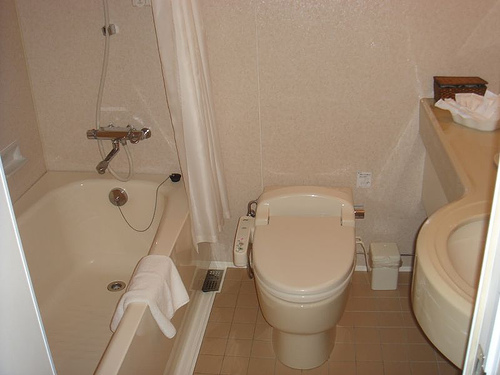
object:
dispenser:
[434, 90, 500, 132]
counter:
[430, 94, 500, 191]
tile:
[228, 320, 260, 339]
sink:
[448, 216, 484, 288]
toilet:
[249, 183, 358, 370]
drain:
[107, 280, 126, 293]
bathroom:
[0, 0, 500, 375]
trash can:
[368, 242, 402, 291]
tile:
[204, 302, 238, 322]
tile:
[228, 303, 259, 323]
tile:
[352, 324, 381, 343]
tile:
[380, 342, 410, 361]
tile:
[376, 308, 405, 327]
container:
[432, 76, 487, 104]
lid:
[249, 210, 357, 295]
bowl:
[251, 276, 354, 333]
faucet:
[85, 122, 150, 175]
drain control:
[108, 188, 129, 206]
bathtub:
[13, 171, 204, 373]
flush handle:
[354, 205, 364, 220]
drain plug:
[169, 173, 181, 182]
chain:
[114, 173, 174, 233]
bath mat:
[108, 251, 190, 338]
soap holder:
[2, 138, 30, 178]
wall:
[2, 1, 48, 205]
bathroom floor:
[190, 271, 461, 375]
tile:
[222, 335, 256, 355]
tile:
[248, 335, 279, 359]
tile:
[353, 340, 383, 363]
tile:
[407, 342, 437, 362]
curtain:
[151, 2, 233, 247]